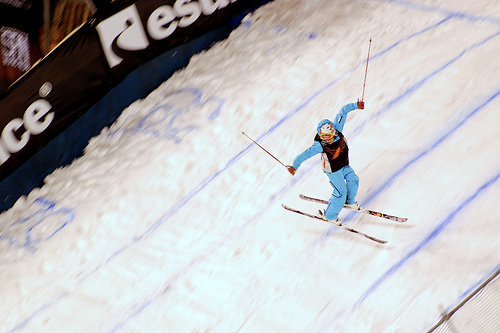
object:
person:
[287, 100, 367, 223]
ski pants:
[322, 165, 361, 220]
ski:
[280, 201, 388, 246]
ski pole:
[360, 37, 375, 100]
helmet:
[318, 121, 337, 140]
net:
[0, 0, 273, 216]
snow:
[0, 0, 500, 332]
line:
[354, 173, 500, 307]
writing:
[93, 0, 239, 68]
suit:
[314, 131, 351, 173]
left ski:
[294, 193, 410, 222]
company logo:
[94, 5, 150, 68]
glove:
[284, 166, 299, 176]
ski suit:
[292, 101, 361, 219]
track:
[254, 3, 299, 38]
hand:
[356, 99, 368, 110]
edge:
[320, 148, 333, 175]